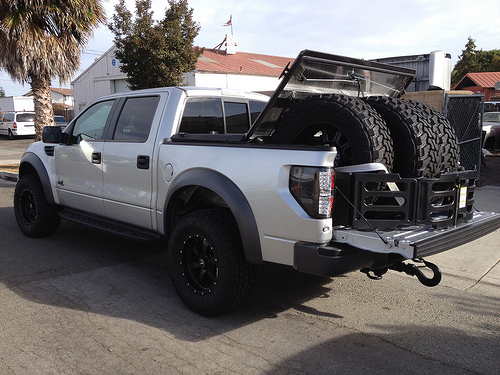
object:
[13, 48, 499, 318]
truck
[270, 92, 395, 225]
tire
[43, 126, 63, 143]
mirror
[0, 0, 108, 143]
tree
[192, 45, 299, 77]
roof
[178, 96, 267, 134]
window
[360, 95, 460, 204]
wheel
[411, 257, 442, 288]
hook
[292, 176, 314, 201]
light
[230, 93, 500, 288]
back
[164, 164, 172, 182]
cap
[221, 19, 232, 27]
flag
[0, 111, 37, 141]
van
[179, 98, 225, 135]
glass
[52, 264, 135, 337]
surface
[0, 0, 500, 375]
photo